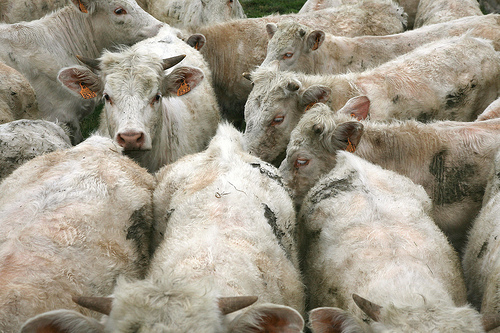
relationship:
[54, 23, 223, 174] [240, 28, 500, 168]
cow next to cow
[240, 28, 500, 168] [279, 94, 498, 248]
cow next to cow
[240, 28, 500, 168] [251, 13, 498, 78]
cow next to cow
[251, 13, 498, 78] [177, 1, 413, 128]
cow next to cow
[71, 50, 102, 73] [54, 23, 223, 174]
horn on cow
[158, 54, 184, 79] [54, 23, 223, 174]
horn on cow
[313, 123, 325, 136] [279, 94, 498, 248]
horn on cow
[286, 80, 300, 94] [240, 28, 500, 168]
horn on cow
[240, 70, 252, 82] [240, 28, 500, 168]
horn on cow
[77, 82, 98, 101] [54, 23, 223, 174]
ear tag on cow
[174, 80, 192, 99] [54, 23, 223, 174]
ear tag on cow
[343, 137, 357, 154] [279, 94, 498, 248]
ear tag on cow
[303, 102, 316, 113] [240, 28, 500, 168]
ear tag on cow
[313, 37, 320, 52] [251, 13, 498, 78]
ear tag on cow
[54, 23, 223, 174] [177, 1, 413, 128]
cow next to cow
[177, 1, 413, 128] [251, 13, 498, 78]
cow next to cow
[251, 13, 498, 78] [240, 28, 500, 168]
cow next to cow